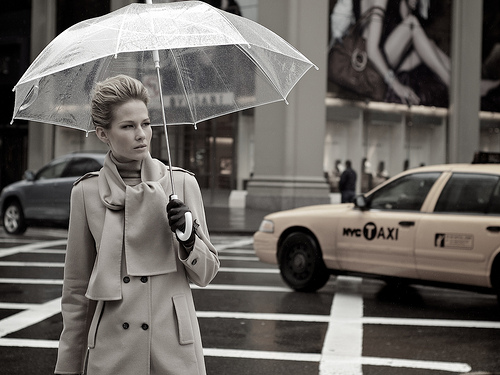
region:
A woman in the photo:
[48, 74, 237, 366]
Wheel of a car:
[267, 232, 323, 292]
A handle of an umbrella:
[156, 137, 192, 219]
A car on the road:
[330, 186, 445, 278]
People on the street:
[320, 143, 392, 193]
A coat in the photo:
[103, 175, 188, 361]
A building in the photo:
[280, 15, 382, 155]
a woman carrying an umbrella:
[9, 3, 319, 273]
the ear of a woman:
[91, 122, 113, 145]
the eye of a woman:
[114, 119, 136, 134]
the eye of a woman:
[141, 113, 152, 132]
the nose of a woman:
[133, 122, 148, 141]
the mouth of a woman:
[133, 140, 150, 152]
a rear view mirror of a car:
[347, 189, 374, 214]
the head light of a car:
[253, 216, 277, 234]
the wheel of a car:
[275, 230, 324, 295]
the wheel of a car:
[0, 194, 30, 234]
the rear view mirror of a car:
[20, 165, 39, 182]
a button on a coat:
[137, 318, 149, 333]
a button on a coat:
[116, 319, 133, 333]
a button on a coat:
[120, 274, 131, 284]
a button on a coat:
[140, 273, 148, 285]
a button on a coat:
[189, 256, 199, 268]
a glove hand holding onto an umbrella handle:
[158, 186, 198, 242]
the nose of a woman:
[132, 122, 147, 147]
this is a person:
[56, 69, 219, 368]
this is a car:
[226, 131, 496, 321]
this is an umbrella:
[5, 3, 330, 118]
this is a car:
[5, 137, 69, 234]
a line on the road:
[210, 347, 330, 367]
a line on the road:
[202, 312, 332, 335]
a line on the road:
[364, 317, 498, 347]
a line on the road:
[225, 264, 288, 327]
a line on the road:
[2, 289, 54, 361]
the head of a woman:
[78, 60, 195, 168]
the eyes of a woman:
[103, 113, 163, 143]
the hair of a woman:
[61, 60, 174, 173]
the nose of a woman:
[128, 133, 155, 150]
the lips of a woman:
[121, 133, 167, 176]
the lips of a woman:
[111, 143, 160, 188]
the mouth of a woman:
[121, 118, 184, 173]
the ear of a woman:
[78, 113, 118, 145]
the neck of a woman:
[101, 152, 142, 199]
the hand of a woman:
[158, 180, 232, 267]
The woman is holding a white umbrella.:
[9, 3, 310, 242]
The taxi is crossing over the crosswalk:
[251, 163, 495, 302]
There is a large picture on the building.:
[326, 0, 460, 112]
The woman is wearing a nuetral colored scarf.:
[83, 151, 179, 301]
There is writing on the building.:
[153, 90, 231, 108]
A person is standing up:
[339, 156, 358, 206]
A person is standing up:
[327, 158, 335, 198]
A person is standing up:
[357, 152, 379, 199]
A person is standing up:
[373, 154, 386, 182]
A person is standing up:
[60, 97, 233, 362]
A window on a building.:
[216, 106, 236, 185]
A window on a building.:
[190, 105, 207, 192]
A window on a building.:
[156, 108, 179, 183]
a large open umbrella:
[11, 7, 326, 239]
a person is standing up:
[53, 76, 213, 373]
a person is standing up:
[335, 157, 360, 205]